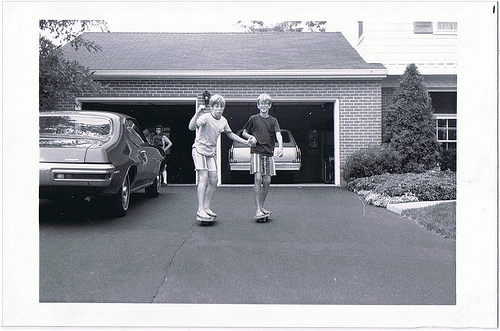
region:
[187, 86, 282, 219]
Two boys holding hands skateboarding.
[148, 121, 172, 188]
Kid standing in the garage with their hand on their hip.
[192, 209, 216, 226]
Skateboard a kid is riding who has his fist in the air.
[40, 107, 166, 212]
Car parked on the left side of the driveway.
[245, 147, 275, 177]
Striped shorts of a kid riding a skateboard to the right of another kid. n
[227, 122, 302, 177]
Station wagon parked in the right side of the garage.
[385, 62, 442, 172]
Pine tree on the right side of the garage.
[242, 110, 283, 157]
Dark t-shirt on a kid with glasses on a skateboard.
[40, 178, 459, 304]
Paved driveway that two kids are skating on.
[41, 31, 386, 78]
Dark roof over a garage.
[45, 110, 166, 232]
car in the driveway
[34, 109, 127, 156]
window on the car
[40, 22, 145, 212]
tree branches above car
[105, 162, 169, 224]
wheel on the car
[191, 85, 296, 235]
two boys in driveway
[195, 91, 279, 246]
boys on the skateboard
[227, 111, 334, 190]
car in the garage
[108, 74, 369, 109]
the garage is brick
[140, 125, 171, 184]
children in front of car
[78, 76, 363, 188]
the two door garage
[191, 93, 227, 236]
boy on skate board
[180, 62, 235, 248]
boy wearing tshirt and shorts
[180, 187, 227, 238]
skate board with wheels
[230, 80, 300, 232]
boy on skate board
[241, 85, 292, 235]
boy wearing tshirt and shorts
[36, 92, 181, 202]
car in drive way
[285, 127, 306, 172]
car in garage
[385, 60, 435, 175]
tree next to house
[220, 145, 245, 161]
tail light on car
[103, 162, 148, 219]
tire on car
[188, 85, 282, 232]
two boys in front of a garage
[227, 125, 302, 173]
car parked in a garage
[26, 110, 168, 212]
car parked in a driveway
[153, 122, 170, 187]
child standing inside a garage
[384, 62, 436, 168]
tall pine tree next to a garage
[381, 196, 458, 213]
white stone walkway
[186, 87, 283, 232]
two boys on skateboards in a driveway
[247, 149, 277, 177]
striped shorts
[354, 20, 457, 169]
house attached to a garage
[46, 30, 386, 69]
black shingles on a garage roof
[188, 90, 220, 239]
this is a boy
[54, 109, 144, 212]
this is a car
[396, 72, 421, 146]
this is a tree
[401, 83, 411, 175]
the leaves are green in color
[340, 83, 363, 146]
this is the wall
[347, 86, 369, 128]
the wall is made of bricks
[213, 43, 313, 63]
this is the roof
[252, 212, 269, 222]
this is a skate board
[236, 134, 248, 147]
the boy is light skinned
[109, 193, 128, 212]
this is a wheel